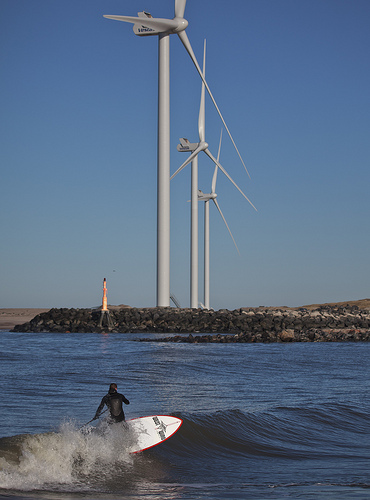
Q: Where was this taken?
A: On the lake.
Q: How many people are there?
A: 1.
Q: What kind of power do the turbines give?
A: Wind.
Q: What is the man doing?
A: Paddleboarding.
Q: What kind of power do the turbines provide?
A: Wind.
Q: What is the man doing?
A: Paddleboarding.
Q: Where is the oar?
A: In the man's hands.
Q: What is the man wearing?
A: Wetsuite.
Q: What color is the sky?
A: Blue.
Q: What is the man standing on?
A: Surfboard.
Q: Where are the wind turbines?
A: On the shore.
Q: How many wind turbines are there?
A: 3.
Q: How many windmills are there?
A: Three.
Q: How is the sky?
A: Blue and clear.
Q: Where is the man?
A: In the water.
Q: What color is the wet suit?
A: Black.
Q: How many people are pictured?
A: One.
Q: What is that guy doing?
A: He is surfing.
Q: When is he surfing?
A: In the daytime.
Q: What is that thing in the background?
A: A windmill.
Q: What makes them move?
A: Wind.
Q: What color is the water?
A: Blue.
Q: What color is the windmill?
A: White.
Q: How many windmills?
A: Three.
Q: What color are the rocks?
A: Black.